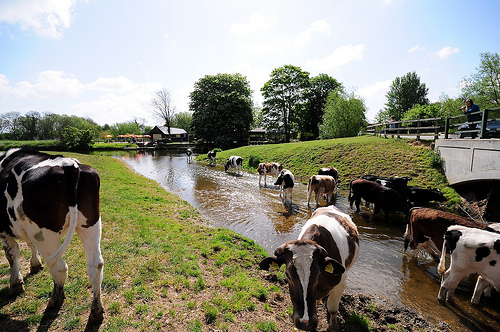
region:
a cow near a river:
[1, 131, 193, 329]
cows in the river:
[388, 190, 498, 328]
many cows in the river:
[115, 136, 495, 330]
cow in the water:
[256, 157, 304, 209]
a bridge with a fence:
[360, 99, 499, 202]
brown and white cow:
[250, 210, 365, 310]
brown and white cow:
[425, 220, 490, 286]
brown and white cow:
[306, 165, 346, 212]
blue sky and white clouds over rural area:
[6, 5, 496, 150]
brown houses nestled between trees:
[7, 77, 302, 150]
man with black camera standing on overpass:
[412, 95, 497, 137]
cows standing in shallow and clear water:
[362, 186, 493, 324]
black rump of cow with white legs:
[5, 138, 109, 325]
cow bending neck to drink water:
[217, 157, 245, 178]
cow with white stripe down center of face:
[283, 239, 325, 328]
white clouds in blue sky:
[42, 32, 87, 54]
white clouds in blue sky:
[442, 21, 469, 41]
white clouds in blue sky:
[360, 6, 404, 41]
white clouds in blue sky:
[252, 28, 272, 45]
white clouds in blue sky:
[302, 0, 357, 32]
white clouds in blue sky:
[157, 15, 218, 66]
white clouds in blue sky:
[73, 40, 103, 76]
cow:
[10, 138, 111, 318]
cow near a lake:
[7, 140, 104, 311]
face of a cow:
[255, 240, 345, 325]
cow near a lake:
[280, 206, 352, 326]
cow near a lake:
[445, 220, 470, 296]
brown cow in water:
[345, 175, 390, 205]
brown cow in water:
[300, 170, 335, 191]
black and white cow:
[275, 170, 296, 205]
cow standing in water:
[217, 150, 247, 175]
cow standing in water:
[174, 144, 201, 166]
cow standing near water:
[253, 200, 359, 325]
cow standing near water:
[0, 136, 105, 326]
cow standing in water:
[450, 226, 497, 291]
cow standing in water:
[402, 200, 440, 246]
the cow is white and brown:
[251, 196, 375, 331]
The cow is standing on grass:
[3, 140, 178, 330]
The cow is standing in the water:
[265, 156, 302, 218]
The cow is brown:
[400, 200, 498, 283]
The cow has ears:
[239, 234, 351, 322]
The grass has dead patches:
[139, 234, 281, 329]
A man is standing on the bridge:
[440, 79, 494, 179]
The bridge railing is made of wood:
[383, 112, 496, 164]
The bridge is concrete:
[408, 127, 498, 204]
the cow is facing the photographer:
[262, 203, 355, 327]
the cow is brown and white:
[274, 201, 359, 330]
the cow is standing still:
[3, 147, 108, 325]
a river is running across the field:
[109, 135, 498, 326]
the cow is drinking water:
[222, 153, 242, 175]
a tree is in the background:
[187, 74, 252, 147]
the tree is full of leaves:
[188, 73, 250, 145]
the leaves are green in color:
[183, 73, 251, 151]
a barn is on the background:
[147, 123, 184, 145]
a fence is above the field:
[371, 108, 498, 143]